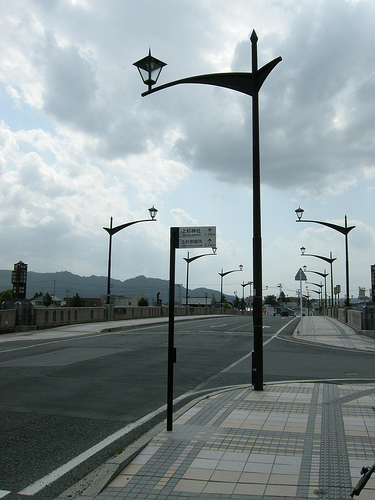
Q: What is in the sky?
A: Clouds.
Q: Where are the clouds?
A: In the sky.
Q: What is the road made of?
A: Asphalt.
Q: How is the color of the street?
A: The street is dark gray in color.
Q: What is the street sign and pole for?
A: The street sign and pole are to know location and direction.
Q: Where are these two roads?
A: Intersection of two roads.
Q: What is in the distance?
A: There are mountains in the distance.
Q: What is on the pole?
A: There is a sign on the pole.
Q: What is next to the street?
A: The sidewalk is next to the street.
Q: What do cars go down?
A: The cars go down the street.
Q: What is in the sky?
A: Clouds.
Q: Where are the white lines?
A: Street.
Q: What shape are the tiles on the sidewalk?
A: Square.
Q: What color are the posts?
A: Black.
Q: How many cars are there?
A: None.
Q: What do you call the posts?
A: Street lights.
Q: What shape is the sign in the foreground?
A: Rectangle.